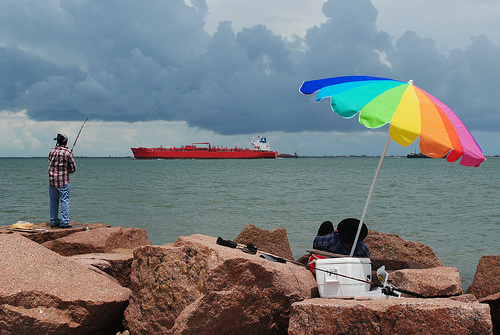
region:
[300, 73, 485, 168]
bright multi-colored umbrella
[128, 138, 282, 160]
long red ship in water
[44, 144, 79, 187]
man in plaid shirt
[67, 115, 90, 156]
man holding fishing pole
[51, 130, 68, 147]
man wearing bandana on head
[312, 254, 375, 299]
man leaning on white cooler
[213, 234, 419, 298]
fishing pole resting near cooler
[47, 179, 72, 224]
man wearing blue jeans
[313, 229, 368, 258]
man wearing blue plaid shirt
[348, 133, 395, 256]
long white pole holding umbrella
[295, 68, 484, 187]
A rainbow colored umbrella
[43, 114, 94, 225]
A man standing on the rocks and fishing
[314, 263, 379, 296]
A white cooler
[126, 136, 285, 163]
A long red ship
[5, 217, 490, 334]
Ragged rocks by the sea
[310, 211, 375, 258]
A man laying down on the rocks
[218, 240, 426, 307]
A fishing rod across the rocks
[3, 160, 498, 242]
A calm blue sea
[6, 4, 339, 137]
A cloudy sky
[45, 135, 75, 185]
A man wearing a checkered shirt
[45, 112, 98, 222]
A person fishing.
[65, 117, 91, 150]
A dark colored fishing pole.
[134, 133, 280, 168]
A large red ship.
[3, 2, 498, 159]
A grey sky with dark blue clouds.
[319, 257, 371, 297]
A white cooler.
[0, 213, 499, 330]
Large brown rocks.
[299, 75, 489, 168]
A multicolored umbrella.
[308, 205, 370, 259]
A person lying on the rocks.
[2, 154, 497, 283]
A body of water.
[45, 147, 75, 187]
A long sleeved red and white plaid shirt.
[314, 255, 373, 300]
white plastic cooler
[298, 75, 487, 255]
rainbow striped colored umbrella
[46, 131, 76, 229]
person wearing jeans and a red plaid shirt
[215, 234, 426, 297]
fish reel lying on the ground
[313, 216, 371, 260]
person lying down on the rocks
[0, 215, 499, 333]
large reddish brown rocks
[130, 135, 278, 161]
red cargo ship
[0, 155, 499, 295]
large body of dark water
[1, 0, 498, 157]
dark overcast sky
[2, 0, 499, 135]
huge bank of dark clouds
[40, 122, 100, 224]
A man fishing on a shore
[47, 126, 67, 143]
A black baseball cap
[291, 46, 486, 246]
A multiple colored umbrella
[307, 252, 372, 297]
A white bait box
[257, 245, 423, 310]
A black fishing rod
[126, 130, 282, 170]
A very large red ship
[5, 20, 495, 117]
A very dark cloud chain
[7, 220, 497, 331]
A shore of red rocks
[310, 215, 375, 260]
A person resting under an umbrella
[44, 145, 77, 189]
A red/white shirt